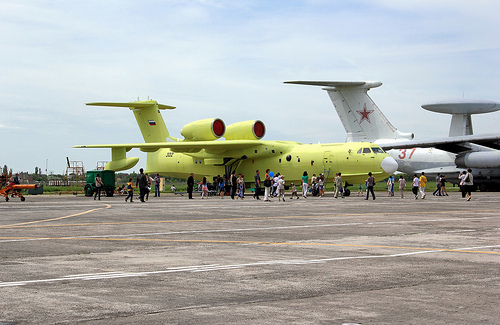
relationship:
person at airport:
[459, 166, 473, 200] [3, 168, 499, 320]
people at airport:
[89, 172, 481, 202] [3, 168, 499, 320]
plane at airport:
[74, 98, 400, 192] [3, 168, 499, 320]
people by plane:
[89, 172, 481, 202] [74, 98, 400, 192]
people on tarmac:
[89, 172, 481, 202] [17, 202, 491, 256]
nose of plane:
[379, 155, 398, 180] [74, 98, 400, 192]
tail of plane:
[86, 98, 189, 162] [74, 98, 400, 192]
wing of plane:
[65, 138, 271, 172] [74, 98, 400, 192]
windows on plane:
[262, 150, 307, 164] [74, 98, 400, 192]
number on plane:
[395, 144, 416, 162] [285, 73, 498, 169]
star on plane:
[353, 102, 374, 126] [285, 73, 498, 169]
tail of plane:
[281, 66, 421, 174] [285, 73, 498, 169]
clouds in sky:
[53, 21, 207, 53] [12, 4, 497, 134]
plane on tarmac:
[74, 98, 400, 192] [17, 202, 491, 256]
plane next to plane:
[285, 73, 498, 169] [74, 98, 400, 192]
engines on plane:
[174, 115, 268, 145] [74, 98, 400, 192]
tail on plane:
[86, 98, 189, 162] [74, 98, 400, 192]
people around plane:
[89, 172, 481, 202] [74, 98, 400, 192]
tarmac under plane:
[17, 202, 491, 256] [74, 98, 400, 192]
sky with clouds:
[12, 4, 497, 134] [53, 21, 207, 53]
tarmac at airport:
[17, 202, 491, 256] [3, 168, 499, 320]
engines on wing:
[174, 115, 268, 145] [65, 138, 271, 172]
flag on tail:
[144, 117, 159, 132] [86, 98, 189, 162]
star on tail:
[353, 102, 374, 126] [281, 66, 421, 174]